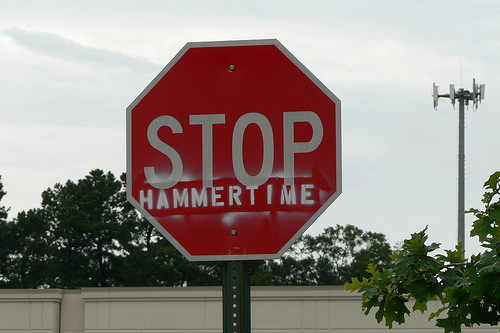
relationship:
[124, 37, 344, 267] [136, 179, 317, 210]
sign has writing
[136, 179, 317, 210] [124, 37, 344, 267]
writing on sign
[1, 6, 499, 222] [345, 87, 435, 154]
clouds in blue sky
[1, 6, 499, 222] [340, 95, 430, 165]
clouds in blue sky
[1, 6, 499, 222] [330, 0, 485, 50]
clouds in blue sky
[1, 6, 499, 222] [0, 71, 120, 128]
clouds in blue sky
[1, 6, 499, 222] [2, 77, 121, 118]
clouds in blue sky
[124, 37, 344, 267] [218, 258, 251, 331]
sign on pole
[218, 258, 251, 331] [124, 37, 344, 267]
pole has sign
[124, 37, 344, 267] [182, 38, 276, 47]
sign has border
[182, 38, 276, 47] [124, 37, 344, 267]
border of sign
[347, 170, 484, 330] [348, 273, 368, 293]
plant has leaf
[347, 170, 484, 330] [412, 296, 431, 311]
plant has leaf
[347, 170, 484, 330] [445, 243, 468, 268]
plant has leaf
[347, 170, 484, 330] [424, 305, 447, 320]
plant has leaf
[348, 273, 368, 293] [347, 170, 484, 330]
leaf on plant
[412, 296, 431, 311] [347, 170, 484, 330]
leaf on plant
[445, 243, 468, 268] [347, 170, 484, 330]
leaf on plant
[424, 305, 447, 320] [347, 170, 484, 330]
leaf on plant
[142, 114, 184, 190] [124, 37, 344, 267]
letter on sign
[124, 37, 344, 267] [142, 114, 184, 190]
sign has letter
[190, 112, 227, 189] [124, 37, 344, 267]
letter t on sign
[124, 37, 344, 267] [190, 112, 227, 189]
sign has letter t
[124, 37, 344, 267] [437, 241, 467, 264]
sign has leaf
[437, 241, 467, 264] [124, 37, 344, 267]
leaf on sign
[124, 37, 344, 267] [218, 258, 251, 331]
sign has pole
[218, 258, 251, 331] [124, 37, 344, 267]
pole on sign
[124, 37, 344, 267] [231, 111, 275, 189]
sign has letter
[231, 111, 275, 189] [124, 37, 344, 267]
letter on sign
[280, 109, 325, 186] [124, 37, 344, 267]
letter on sign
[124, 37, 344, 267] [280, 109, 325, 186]
sign has letter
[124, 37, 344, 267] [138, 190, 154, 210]
sign has white letter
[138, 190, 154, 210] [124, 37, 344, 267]
white letter on sign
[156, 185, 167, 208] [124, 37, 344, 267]
white letter on sign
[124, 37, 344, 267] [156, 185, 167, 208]
sign has white letter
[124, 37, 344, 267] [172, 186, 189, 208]
sign has white letter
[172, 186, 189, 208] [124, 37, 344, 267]
white letter on sign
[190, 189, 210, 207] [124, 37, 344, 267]
white letter on sign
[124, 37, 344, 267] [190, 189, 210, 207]
sign has white letter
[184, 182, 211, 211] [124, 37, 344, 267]
letter on sign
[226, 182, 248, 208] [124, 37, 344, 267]
letter on sign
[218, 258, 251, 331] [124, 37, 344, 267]
pole for sign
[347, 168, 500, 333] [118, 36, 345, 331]
plant closest to sign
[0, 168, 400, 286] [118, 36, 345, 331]
trees are behind sign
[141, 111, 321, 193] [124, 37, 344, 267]
word on sign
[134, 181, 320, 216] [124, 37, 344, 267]
paint on sign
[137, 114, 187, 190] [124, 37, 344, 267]
letter on sign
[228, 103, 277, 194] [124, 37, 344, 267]
letter on sign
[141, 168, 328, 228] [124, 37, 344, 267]
graffiti on sign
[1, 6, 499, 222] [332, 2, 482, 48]
clouds are on blue sky